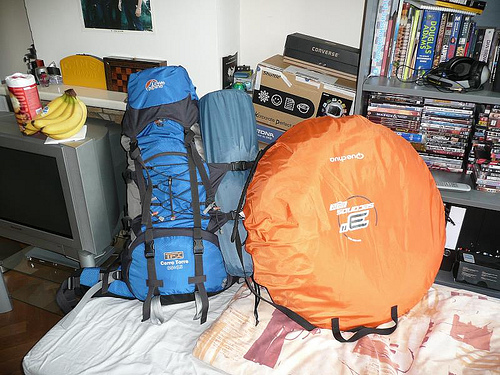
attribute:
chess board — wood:
[108, 55, 145, 90]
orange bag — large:
[252, 99, 457, 341]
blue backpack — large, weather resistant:
[82, 62, 222, 302]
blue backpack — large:
[100, 72, 237, 312]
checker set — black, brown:
[102, 58, 166, 93]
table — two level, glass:
[2, 247, 77, 309]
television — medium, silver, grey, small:
[0, 110, 125, 273]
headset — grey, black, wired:
[394, 55, 490, 95]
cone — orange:
[210, 111, 446, 343]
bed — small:
[61, 279, 481, 374]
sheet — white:
[58, 299, 222, 373]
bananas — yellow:
[15, 87, 88, 140]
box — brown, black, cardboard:
[239, 47, 367, 145]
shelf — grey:
[366, 71, 427, 111]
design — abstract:
[244, 278, 499, 373]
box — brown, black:
[281, 31, 368, 76]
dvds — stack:
[353, 5, 498, 215]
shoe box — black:
[282, 29, 363, 76]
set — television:
[0, 83, 129, 285]